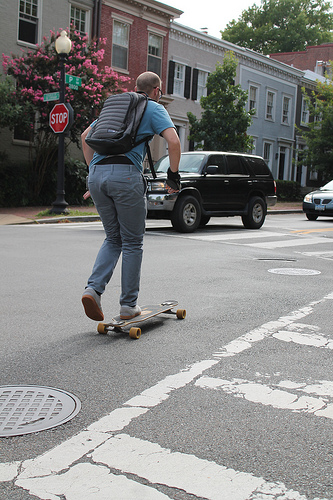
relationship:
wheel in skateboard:
[127, 325, 140, 338] [96, 297, 188, 339]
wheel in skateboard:
[177, 309, 183, 318] [96, 297, 188, 339]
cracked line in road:
[179, 332, 299, 446] [0, 224, 333, 456]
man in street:
[79, 71, 181, 324] [158, 279, 226, 360]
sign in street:
[47, 102, 70, 133] [11, 218, 332, 365]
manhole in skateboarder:
[2, 381, 83, 440] [75, 69, 189, 339]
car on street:
[142, 149, 278, 232] [12, 222, 331, 435]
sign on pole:
[60, 71, 87, 94] [54, 50, 73, 209]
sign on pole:
[41, 89, 61, 104] [54, 50, 73, 209]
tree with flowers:
[0, 17, 134, 235] [4, 19, 131, 126]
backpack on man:
[84, 89, 148, 156] [79, 71, 181, 324]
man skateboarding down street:
[79, 71, 181, 324] [12, 222, 331, 435]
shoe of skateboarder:
[80, 287, 103, 321] [75, 69, 189, 339]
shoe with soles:
[80, 287, 103, 321] [80, 293, 103, 322]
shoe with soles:
[80, 287, 103, 321] [119, 313, 138, 318]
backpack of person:
[83, 87, 155, 156] [76, 68, 184, 329]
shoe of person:
[79, 287, 109, 329] [76, 68, 184, 329]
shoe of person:
[116, 299, 144, 319] [76, 68, 184, 329]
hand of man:
[161, 165, 186, 196] [79, 71, 181, 324]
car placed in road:
[138, 145, 289, 233] [18, 224, 327, 456]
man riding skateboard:
[79, 71, 181, 324] [96, 297, 188, 339]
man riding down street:
[79, 71, 181, 324] [10, 227, 329, 411]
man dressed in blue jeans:
[79, 71, 181, 324] [82, 163, 150, 318]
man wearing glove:
[79, 71, 181, 324] [164, 165, 185, 189]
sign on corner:
[48, 102, 69, 133] [6, 207, 92, 243]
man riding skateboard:
[71, 71, 187, 342] [96, 297, 188, 339]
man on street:
[71, 71, 187, 342] [2, 213, 331, 495]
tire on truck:
[242, 195, 265, 228] [145, 151, 277, 230]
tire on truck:
[174, 191, 201, 233] [145, 151, 277, 230]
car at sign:
[142, 149, 278, 232] [44, 102, 72, 130]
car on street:
[142, 149, 278, 232] [8, 219, 326, 421]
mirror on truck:
[204, 161, 220, 177] [175, 152, 260, 212]